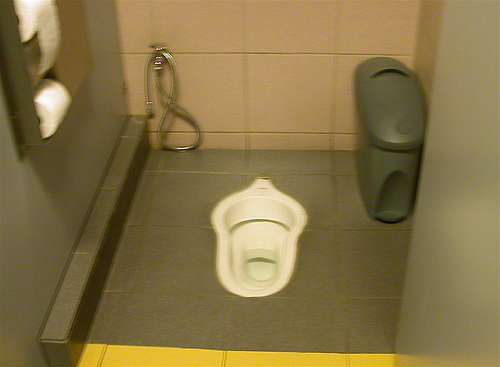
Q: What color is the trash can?
A: Gray.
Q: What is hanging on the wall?
A: Toilet paper.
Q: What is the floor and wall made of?
A: Tile.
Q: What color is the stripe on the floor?
A: Yellow.